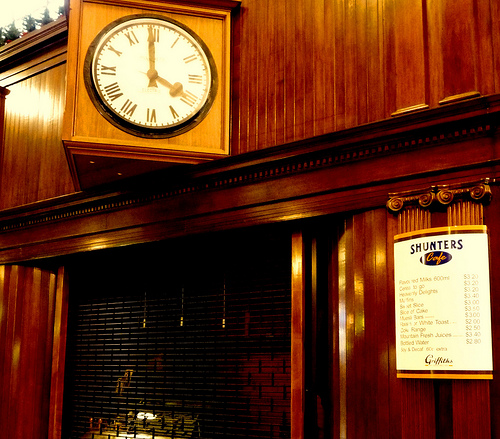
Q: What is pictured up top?
A: Clock.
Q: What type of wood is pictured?
A: Oak.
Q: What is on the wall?
A: Menu.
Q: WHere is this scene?
A: Restaurant.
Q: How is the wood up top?
A: Panels.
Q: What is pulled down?
A: Gate.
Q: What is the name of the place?
A: Shutters.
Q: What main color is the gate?
A: Black.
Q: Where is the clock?
A: Above the door.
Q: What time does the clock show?
A: 4:00.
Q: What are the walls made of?
A: Wood.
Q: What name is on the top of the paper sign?
A: SHUNTERS.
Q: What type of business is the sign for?
A: Cafe.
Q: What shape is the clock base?
A: Triangle.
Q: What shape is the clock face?
A: Round.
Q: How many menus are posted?
A: 1.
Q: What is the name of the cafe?
A: Shunters Cafe.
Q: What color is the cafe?
A: Brown.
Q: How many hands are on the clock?
A: 2.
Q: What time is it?
A: 4:00.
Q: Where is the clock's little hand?
A: On the 4.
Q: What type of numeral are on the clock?
A: Roman.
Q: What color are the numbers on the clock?
A: Black.